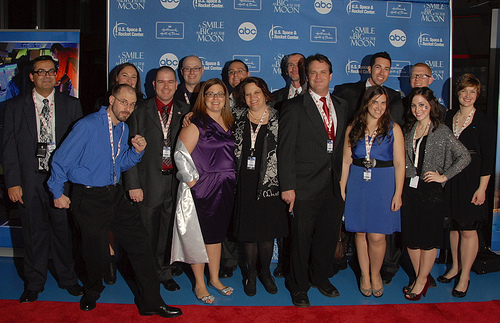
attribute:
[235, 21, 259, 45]
logo — abc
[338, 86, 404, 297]
woman — attending, here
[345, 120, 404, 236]
dress — blue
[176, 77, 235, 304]
woman — attending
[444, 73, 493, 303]
woman — attending, here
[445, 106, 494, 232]
dress — black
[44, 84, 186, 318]
man — posing, attending, here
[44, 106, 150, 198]
shirt — blue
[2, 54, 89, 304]
man — black, here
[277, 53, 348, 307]
man — here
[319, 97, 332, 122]
tie — red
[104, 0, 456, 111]
background — blue, white, large, sponsors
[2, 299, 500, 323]
carpet — red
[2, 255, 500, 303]
floor — blue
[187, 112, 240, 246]
dress — purple